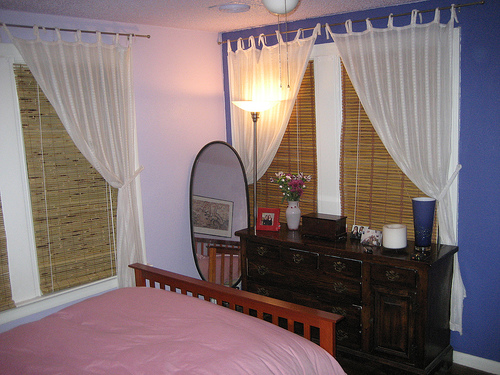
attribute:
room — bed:
[9, 37, 473, 367]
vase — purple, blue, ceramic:
[404, 197, 436, 253]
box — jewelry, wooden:
[302, 208, 364, 244]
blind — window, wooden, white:
[236, 59, 342, 228]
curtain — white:
[38, 25, 140, 183]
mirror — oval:
[160, 120, 296, 282]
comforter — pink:
[30, 293, 182, 360]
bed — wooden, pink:
[103, 234, 339, 316]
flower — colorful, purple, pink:
[280, 169, 310, 202]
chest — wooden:
[303, 214, 334, 231]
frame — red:
[243, 196, 287, 244]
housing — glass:
[237, 107, 269, 114]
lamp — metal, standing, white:
[226, 87, 280, 220]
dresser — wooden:
[226, 220, 440, 317]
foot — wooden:
[111, 247, 194, 314]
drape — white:
[76, 31, 146, 122]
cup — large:
[385, 191, 451, 261]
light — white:
[228, 82, 285, 118]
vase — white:
[289, 197, 296, 238]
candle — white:
[381, 223, 407, 256]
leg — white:
[107, 189, 159, 280]